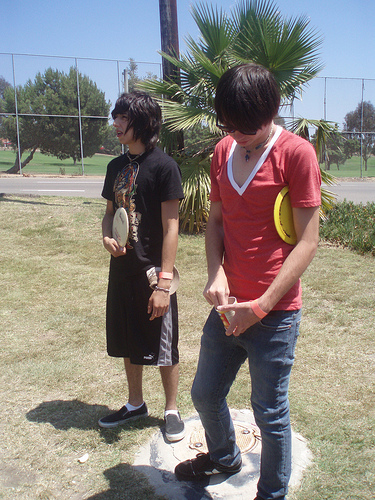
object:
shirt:
[209, 125, 322, 310]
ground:
[0, 193, 374, 498]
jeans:
[190, 305, 303, 500]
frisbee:
[273, 185, 298, 246]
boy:
[97, 89, 185, 441]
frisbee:
[111, 206, 130, 248]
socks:
[123, 400, 146, 410]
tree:
[133, 0, 348, 235]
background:
[0, 0, 374, 258]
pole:
[159, 0, 185, 157]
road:
[0, 172, 117, 197]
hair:
[214, 62, 281, 132]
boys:
[175, 62, 322, 499]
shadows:
[26, 398, 166, 443]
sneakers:
[164, 407, 187, 442]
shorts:
[105, 253, 179, 366]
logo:
[143, 352, 155, 360]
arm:
[263, 148, 322, 342]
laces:
[191, 451, 211, 471]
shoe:
[175, 452, 243, 482]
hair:
[111, 90, 162, 155]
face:
[112, 112, 134, 146]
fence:
[0, 51, 374, 182]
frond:
[242, 0, 327, 83]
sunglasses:
[214, 115, 264, 135]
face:
[220, 110, 264, 150]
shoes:
[97, 400, 150, 428]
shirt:
[101, 145, 186, 273]